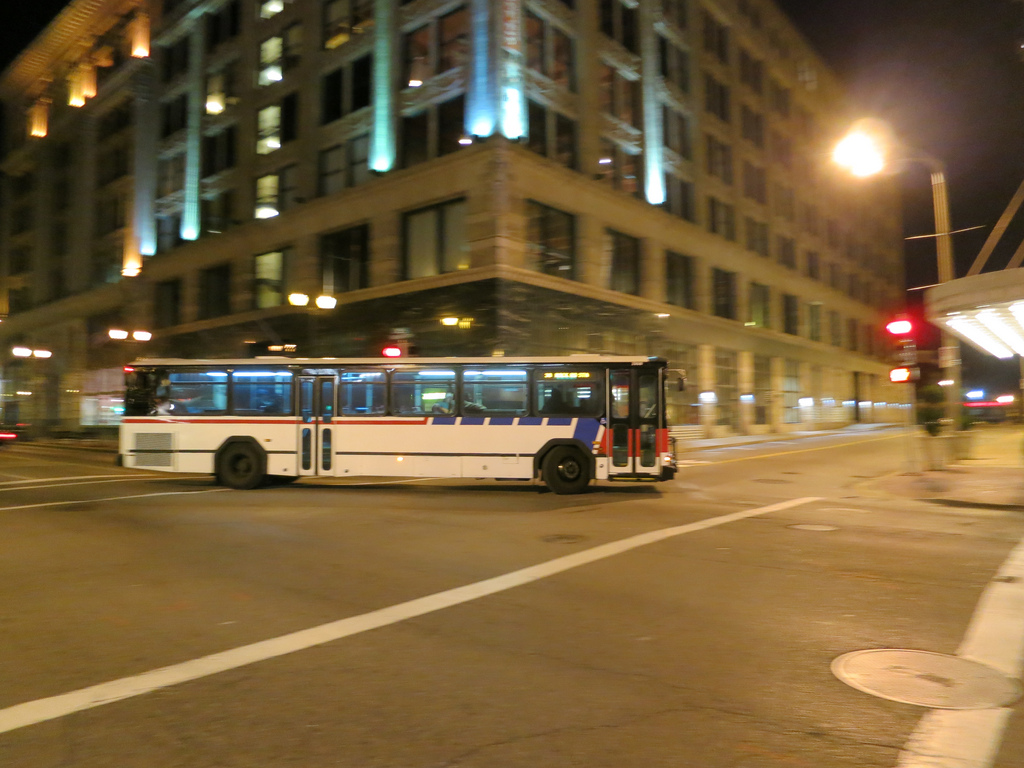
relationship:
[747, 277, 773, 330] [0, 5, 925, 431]
window on building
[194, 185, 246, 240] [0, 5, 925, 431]
window 10 on building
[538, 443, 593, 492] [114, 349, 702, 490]
front wheel of bus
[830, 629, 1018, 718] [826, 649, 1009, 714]
top of man hole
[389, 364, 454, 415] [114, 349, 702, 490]
window on bus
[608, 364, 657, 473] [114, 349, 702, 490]
door on bus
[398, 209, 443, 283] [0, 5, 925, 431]
window on building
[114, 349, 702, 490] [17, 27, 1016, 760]
bus in city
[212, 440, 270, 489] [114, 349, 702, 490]
tire of bus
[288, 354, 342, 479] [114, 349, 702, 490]
door of bus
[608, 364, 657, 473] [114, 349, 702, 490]
door of bus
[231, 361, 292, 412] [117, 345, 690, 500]
window on bus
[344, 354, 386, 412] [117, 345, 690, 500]
window on bus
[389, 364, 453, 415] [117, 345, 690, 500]
window on bus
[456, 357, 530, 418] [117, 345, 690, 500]
window on bus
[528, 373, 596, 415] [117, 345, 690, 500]
window on bus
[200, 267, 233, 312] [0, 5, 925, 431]
window on building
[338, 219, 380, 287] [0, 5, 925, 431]
window on building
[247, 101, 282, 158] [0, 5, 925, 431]
window on building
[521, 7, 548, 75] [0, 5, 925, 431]
window on building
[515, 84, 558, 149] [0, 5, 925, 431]
window on building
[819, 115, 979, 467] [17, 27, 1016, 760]
street light in city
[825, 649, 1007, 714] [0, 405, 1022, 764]
man hole on street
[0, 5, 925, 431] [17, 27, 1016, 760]
building in city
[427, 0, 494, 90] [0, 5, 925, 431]
window on building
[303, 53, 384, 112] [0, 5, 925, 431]
window on building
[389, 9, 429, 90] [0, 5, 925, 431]
window on building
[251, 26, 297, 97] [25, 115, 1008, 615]
window 4 on building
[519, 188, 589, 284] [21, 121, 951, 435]
window 5 on building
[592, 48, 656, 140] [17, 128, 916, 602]
window 6 on building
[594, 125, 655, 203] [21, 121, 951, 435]
window 7 on building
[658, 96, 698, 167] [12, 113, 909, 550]
window 8 on building